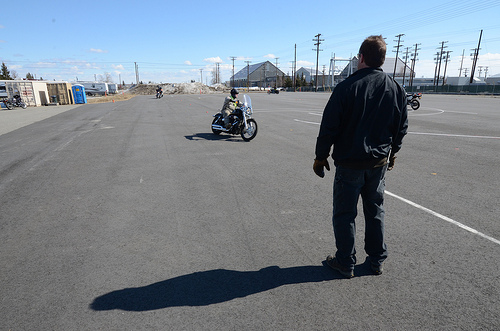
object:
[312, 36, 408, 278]
man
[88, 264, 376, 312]
shadow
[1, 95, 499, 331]
ground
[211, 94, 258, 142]
motor cycle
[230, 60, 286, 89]
building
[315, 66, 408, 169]
jacket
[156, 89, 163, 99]
bike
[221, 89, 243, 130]
man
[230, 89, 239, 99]
helmet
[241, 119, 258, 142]
wheel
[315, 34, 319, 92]
pole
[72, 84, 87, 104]
portapotty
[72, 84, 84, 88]
roof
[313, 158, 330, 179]
glove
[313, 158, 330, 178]
hand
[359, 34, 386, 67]
hair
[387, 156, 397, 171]
hand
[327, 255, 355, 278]
foot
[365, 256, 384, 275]
foot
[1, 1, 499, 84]
sky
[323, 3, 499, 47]
wires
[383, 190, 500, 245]
line